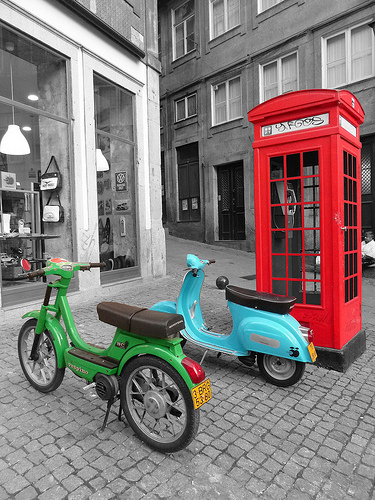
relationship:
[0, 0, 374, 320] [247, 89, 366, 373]
store behind phone booth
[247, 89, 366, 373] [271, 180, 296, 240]
phone booth for phone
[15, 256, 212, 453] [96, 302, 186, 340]
scooter has a seat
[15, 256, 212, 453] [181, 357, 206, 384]
scooter has a tail light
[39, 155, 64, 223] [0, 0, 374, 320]
handbags in store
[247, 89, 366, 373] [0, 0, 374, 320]
phone booth in front of store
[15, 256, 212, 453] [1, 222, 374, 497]
scooter on sidewalk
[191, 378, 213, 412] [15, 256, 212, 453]
license plate on scooter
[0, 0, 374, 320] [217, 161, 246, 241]
store has a door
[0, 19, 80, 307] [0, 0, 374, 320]
window for store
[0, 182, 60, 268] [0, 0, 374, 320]
shelf in store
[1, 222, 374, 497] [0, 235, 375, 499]
sidewalk made of cobble stones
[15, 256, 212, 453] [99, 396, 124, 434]
scooter has a kickstand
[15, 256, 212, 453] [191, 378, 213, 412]
scooter has a license plate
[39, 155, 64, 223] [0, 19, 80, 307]
handbags in window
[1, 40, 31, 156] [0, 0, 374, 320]
light in store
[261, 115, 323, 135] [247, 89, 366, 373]
graffiti on phone booth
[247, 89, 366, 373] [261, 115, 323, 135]
phone booth has graffiti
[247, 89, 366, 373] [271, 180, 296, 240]
phone booth has a phone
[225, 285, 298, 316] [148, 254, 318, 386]
seat on scooter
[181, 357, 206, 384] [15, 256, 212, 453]
tail light on scooter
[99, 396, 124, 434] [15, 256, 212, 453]
kickstand under scooter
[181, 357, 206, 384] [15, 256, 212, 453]
tail light on back of scooter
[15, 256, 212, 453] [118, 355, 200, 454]
scooter has a wheel